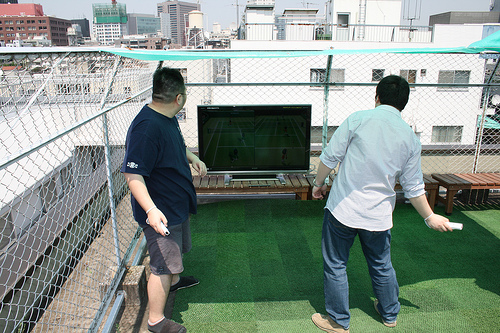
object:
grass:
[173, 193, 500, 332]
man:
[117, 66, 213, 332]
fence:
[0, 48, 158, 333]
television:
[196, 103, 313, 176]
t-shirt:
[120, 103, 200, 227]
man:
[307, 72, 456, 333]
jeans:
[320, 208, 400, 330]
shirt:
[320, 106, 435, 234]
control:
[427, 221, 464, 231]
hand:
[426, 213, 452, 232]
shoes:
[144, 315, 192, 333]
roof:
[0, 144, 499, 333]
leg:
[146, 268, 173, 323]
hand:
[145, 208, 168, 237]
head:
[151, 67, 187, 113]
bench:
[190, 172, 311, 202]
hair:
[375, 75, 411, 112]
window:
[434, 69, 473, 92]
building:
[210, 40, 486, 147]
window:
[430, 124, 464, 143]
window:
[310, 67, 347, 90]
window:
[210, 56, 231, 83]